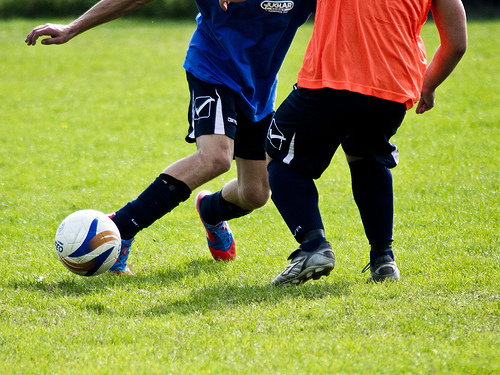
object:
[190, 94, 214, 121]
branding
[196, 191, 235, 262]
shoe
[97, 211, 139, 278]
shoe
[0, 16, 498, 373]
ground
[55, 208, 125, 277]
ball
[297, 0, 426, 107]
orange shirt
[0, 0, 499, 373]
grass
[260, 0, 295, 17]
logo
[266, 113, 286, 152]
logo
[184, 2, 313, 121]
blue shirt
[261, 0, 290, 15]
letters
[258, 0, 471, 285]
man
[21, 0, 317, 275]
man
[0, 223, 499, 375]
shadow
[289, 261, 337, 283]
cleat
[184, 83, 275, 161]
shorts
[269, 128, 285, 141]
white check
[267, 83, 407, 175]
black shorts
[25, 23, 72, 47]
hand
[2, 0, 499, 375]
field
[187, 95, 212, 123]
print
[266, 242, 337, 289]
shoes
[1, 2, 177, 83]
air